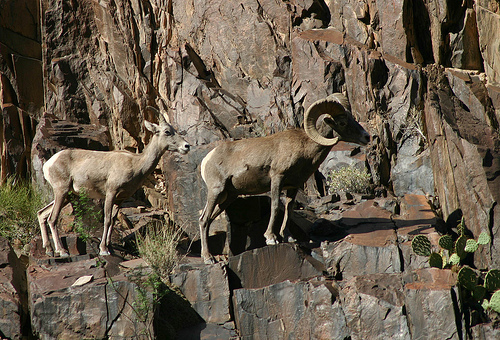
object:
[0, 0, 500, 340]
landscape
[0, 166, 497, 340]
hills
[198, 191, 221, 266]
leg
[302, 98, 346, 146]
horns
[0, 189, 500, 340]
ground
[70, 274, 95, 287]
white rock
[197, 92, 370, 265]
animal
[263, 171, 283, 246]
leg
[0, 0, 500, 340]
wall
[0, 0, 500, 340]
crack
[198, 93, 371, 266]
male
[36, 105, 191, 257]
female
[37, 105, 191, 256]
animals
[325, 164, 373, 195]
flowering weed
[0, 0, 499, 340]
hillface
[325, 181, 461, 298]
stone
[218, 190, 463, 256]
shadow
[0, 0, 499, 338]
rocks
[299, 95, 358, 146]
ram head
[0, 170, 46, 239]
bushes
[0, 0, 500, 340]
rock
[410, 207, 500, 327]
cacti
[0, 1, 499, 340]
rockface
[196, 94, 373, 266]
ram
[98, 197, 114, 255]
leg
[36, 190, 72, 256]
leg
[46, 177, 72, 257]
leg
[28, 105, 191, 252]
ram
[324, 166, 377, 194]
bush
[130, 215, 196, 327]
vegetation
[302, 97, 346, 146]
curved horn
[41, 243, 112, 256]
four hooves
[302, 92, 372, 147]
head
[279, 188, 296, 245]
leg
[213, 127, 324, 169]
brown fur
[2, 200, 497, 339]
side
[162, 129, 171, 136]
eye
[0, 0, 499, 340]
cliff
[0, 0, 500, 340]
habitat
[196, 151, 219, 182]
rear end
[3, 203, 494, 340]
ledge